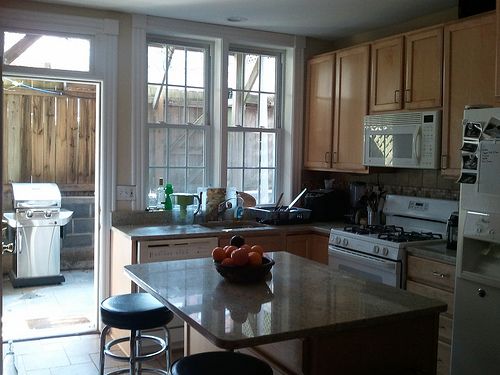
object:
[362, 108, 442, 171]
microwave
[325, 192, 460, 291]
range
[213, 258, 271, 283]
bowl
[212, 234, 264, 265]
fruit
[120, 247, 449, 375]
table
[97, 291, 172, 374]
stool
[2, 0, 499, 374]
kitchen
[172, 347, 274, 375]
stool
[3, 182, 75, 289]
outdoor grill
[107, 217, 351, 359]
counter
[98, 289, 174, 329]
cushion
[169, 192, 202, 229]
water pitcher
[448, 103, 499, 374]
icemaker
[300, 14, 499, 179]
cabinets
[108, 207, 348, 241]
counter top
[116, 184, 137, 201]
switchplate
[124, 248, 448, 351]
counter top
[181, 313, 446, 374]
island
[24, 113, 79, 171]
wall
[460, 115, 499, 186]
pictures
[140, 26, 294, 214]
window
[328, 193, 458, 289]
oven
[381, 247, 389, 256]
knobs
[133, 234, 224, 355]
dishwasher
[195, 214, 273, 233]
sink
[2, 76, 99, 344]
door